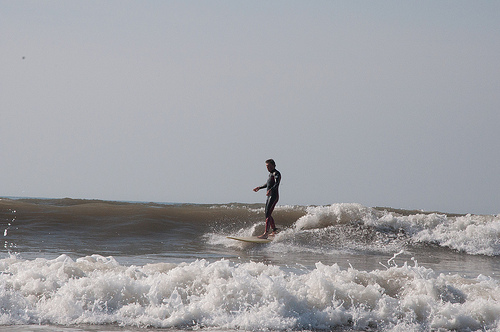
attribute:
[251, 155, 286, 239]
man — surf boarding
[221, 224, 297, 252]
surfboard — white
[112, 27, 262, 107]
gray sky — overhead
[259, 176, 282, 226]
wetsuit — shiny black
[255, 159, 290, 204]
surfer — male